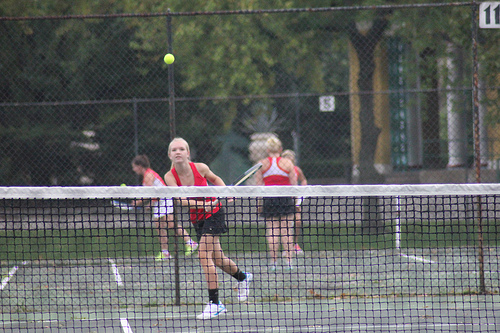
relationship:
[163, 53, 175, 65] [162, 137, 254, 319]
ball hit by girl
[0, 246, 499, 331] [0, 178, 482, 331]
court beyond fence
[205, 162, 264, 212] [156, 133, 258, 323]
racket held by girl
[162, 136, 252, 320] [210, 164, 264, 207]
girl holding racket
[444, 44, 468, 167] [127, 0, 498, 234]
column behind tree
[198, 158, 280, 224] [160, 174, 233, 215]
racket in hand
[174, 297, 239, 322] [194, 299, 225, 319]
shoe on foot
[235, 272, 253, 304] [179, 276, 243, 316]
shoe on foot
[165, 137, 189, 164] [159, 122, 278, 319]
head of girl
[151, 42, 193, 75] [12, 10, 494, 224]
ball in air